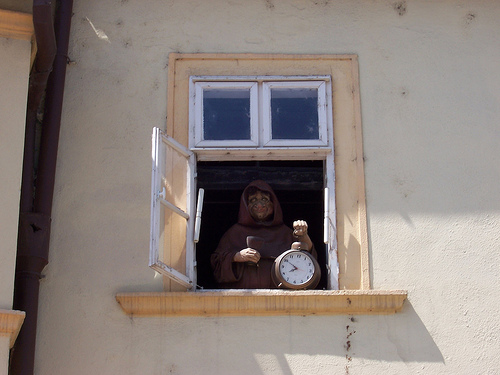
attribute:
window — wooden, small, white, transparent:
[260, 77, 330, 149]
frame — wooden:
[319, 79, 330, 149]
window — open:
[152, 130, 198, 276]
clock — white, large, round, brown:
[271, 249, 322, 288]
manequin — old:
[212, 181, 320, 292]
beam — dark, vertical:
[22, 1, 70, 279]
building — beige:
[21, 9, 474, 150]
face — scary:
[245, 185, 273, 220]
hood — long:
[273, 188, 283, 227]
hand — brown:
[234, 248, 260, 265]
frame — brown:
[337, 61, 363, 290]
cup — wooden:
[245, 233, 265, 250]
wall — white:
[375, 12, 497, 285]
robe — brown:
[221, 221, 286, 259]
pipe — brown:
[16, 5, 77, 373]